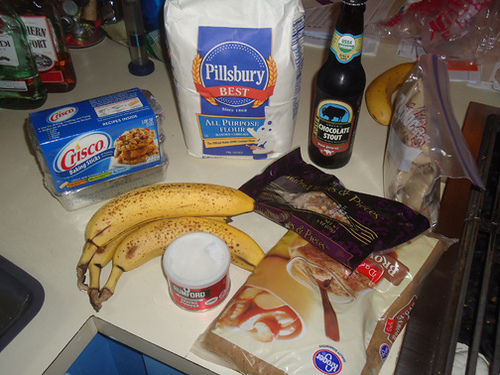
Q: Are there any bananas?
A: Yes, there are bananas.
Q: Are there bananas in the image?
A: Yes, there are bananas.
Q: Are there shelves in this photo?
A: No, there are no shelves.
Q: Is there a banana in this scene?
A: Yes, there is a banana.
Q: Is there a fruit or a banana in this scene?
A: Yes, there is a banana.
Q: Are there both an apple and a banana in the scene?
A: No, there is a banana but no apples.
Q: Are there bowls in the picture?
A: No, there are no bowls.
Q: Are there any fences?
A: No, there are no fences.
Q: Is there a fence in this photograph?
A: No, there are no fences.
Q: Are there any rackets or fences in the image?
A: No, there are no fences or rackets.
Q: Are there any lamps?
A: No, there are no lamps.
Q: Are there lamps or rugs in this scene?
A: No, there are no lamps or rugs.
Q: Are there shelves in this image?
A: No, there are no shelves.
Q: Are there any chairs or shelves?
A: No, there are no shelves or chairs.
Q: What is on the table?
A: The bottles are on the table.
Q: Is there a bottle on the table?
A: Yes, there are bottles on the table.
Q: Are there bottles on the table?
A: Yes, there are bottles on the table.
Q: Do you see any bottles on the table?
A: Yes, there are bottles on the table.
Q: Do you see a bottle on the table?
A: Yes, there are bottles on the table.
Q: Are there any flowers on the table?
A: No, there are bottles on the table.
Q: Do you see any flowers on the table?
A: No, there are bottles on the table.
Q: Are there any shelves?
A: No, there are no shelves.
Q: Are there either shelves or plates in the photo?
A: No, there are no shelves or plates.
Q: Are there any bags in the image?
A: Yes, there is a bag.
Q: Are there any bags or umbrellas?
A: Yes, there is a bag.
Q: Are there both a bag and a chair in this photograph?
A: No, there is a bag but no chairs.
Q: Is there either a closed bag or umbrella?
A: Yes, there is a closed bag.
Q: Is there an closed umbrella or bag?
A: Yes, there is a closed bag.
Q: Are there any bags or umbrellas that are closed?
A: Yes, the bag is closed.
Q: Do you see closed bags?
A: Yes, there is a closed bag.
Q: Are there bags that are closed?
A: Yes, there is a bag that is closed.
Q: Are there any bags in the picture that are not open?
A: Yes, there is an closed bag.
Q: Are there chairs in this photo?
A: No, there are no chairs.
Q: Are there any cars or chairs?
A: No, there are no chairs or cars.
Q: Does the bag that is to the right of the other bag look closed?
A: Yes, the bag is closed.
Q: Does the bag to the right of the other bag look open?
A: No, the bag is closed.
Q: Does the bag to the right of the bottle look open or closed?
A: The bag is closed.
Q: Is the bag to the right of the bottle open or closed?
A: The bag is closed.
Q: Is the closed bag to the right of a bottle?
A: Yes, the bag is to the right of a bottle.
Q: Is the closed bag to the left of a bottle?
A: No, the bag is to the right of a bottle.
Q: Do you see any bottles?
A: Yes, there is a bottle.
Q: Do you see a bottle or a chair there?
A: Yes, there is a bottle.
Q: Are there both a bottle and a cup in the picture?
A: No, there is a bottle but no cups.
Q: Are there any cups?
A: No, there are no cups.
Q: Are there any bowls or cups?
A: No, there are no cups or bowls.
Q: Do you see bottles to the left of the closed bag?
A: Yes, there is a bottle to the left of the bag.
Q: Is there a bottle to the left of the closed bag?
A: Yes, there is a bottle to the left of the bag.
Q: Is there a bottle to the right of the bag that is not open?
A: No, the bottle is to the left of the bag.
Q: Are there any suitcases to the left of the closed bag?
A: No, there is a bottle to the left of the bag.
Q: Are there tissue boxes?
A: No, there are no tissue boxes.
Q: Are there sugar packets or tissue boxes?
A: No, there are no tissue boxes or sugar packets.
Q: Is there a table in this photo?
A: Yes, there is a table.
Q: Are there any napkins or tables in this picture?
A: Yes, there is a table.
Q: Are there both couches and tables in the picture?
A: No, there is a table but no couches.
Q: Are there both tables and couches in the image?
A: No, there is a table but no couches.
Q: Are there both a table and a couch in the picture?
A: No, there is a table but no couches.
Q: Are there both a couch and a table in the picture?
A: No, there is a table but no couches.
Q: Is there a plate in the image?
A: No, there are no plates.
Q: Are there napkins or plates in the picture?
A: No, there are no plates or napkins.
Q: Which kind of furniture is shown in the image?
A: The furniture is a table.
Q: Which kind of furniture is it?
A: The piece of furniture is a table.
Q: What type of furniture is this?
A: This is a table.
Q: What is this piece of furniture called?
A: This is a table.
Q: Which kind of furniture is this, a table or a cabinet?
A: This is a table.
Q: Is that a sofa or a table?
A: That is a table.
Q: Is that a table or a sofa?
A: That is a table.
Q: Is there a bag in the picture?
A: Yes, there is a bag.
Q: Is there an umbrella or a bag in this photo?
A: Yes, there is a bag.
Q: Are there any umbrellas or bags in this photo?
A: Yes, there is a bag.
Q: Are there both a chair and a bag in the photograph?
A: No, there is a bag but no chairs.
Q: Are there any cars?
A: No, there are no cars.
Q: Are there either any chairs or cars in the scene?
A: No, there are no cars or chairs.